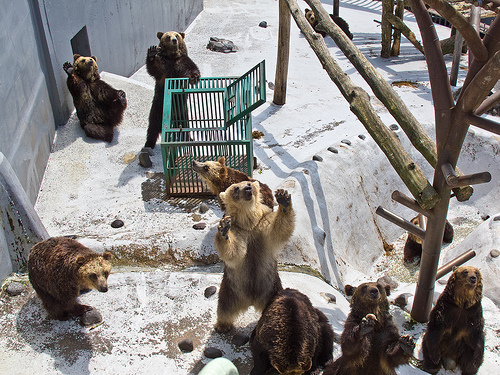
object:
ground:
[0, 0, 500, 375]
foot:
[115, 89, 128, 108]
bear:
[59, 52, 128, 143]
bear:
[190, 157, 275, 211]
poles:
[272, 0, 291, 106]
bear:
[26, 236, 113, 320]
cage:
[160, 60, 266, 199]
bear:
[213, 178, 295, 330]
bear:
[249, 288, 333, 375]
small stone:
[205, 36, 238, 55]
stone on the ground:
[201, 346, 222, 359]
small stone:
[320, 291, 338, 304]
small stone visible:
[488, 248, 498, 258]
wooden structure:
[269, 0, 499, 325]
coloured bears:
[404, 211, 454, 263]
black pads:
[398, 334, 416, 353]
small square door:
[222, 59, 267, 126]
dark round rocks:
[313, 155, 325, 162]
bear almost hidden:
[303, 8, 354, 40]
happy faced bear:
[420, 264, 485, 374]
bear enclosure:
[0, 0, 499, 375]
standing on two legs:
[211, 291, 237, 336]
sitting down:
[58, 52, 127, 142]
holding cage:
[183, 67, 203, 85]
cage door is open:
[168, 59, 266, 129]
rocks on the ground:
[192, 222, 206, 231]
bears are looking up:
[333, 281, 415, 375]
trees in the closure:
[406, 0, 500, 324]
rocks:
[177, 337, 194, 353]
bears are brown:
[144, 31, 200, 149]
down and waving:
[336, 278, 415, 375]